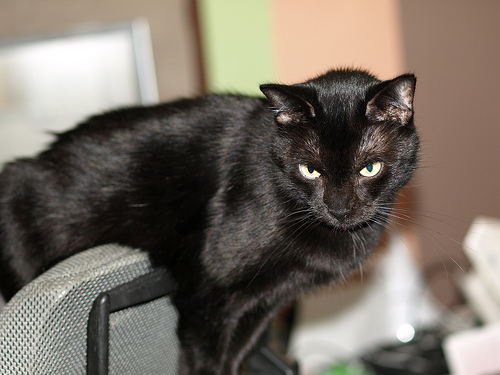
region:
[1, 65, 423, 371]
Black cat on the chair.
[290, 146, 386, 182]
Yellow eyes on the cat.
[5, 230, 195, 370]
Gray office chair.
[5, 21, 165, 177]
Monitor on the desk.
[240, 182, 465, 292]
White whiskers on the cat.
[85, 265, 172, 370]
black frame on the chair.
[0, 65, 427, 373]
Black hair on the cat.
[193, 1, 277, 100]
Green color on the wall.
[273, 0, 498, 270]
Peach color on the wall.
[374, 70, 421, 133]
left ear of the cat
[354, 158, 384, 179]
left eye of the cat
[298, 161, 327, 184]
right eye of the cat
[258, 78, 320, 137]
right ear of the cat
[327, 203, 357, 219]
the cat's black nose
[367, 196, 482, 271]
whiskers coming from left side of cat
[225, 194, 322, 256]
whiskers coming from cat's right side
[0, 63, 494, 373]
black cat laying on gray object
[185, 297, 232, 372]
cat's front right leg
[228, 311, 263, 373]
the cat's left front leg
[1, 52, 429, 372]
THIS CAT LOOKS ANGRY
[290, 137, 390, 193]
THIS CAT HAS BRIGHT EYES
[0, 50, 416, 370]
THIS CAT IS ON THE GREY CHAIR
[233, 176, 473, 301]
THIS CAT HAS LONG WHISKERS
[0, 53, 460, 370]
THIS CAT LOOKS SLEEPY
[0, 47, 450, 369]
THIS CAT IS FURRY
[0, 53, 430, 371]
THIS CAT IS BLACK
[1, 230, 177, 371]
NO ONE IS SITTING IN THIS CHAIR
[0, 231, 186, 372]
THE CHAIR IS GREY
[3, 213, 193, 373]
THE CHAIR HAS A FABRIC UPHOLSTERY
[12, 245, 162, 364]
a grey chair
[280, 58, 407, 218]
the face of the cat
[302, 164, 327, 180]
the eye of the cat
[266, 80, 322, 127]
the ear of the cat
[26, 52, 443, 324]
a cat with green eyes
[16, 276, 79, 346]
the fabric of the chair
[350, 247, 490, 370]
some items on a desk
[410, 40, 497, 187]
a brown wall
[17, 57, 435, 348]
black cat with white eyes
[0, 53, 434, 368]
black cat with white eyes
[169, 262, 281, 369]
cat has a leg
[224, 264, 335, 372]
cat has a leg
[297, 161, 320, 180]
cat has an eye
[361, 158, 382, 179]
cat has an eye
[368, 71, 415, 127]
cat has an ear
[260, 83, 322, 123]
cat has an ear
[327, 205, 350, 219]
cat has a nose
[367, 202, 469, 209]
cat has a wisker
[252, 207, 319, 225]
cat has a wisker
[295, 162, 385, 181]
black cat has yellow eyes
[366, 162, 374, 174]
black pupil in center of eye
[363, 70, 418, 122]
cat has left ear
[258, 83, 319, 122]
cat has a right ear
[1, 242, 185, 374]
gray chair cushion under cat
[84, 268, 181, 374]
black chair frame under cat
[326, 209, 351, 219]
black velvety nose